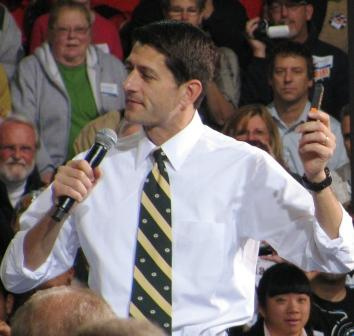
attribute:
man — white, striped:
[83, 68, 260, 252]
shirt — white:
[126, 155, 240, 271]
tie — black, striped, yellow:
[128, 159, 191, 275]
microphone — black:
[83, 137, 116, 169]